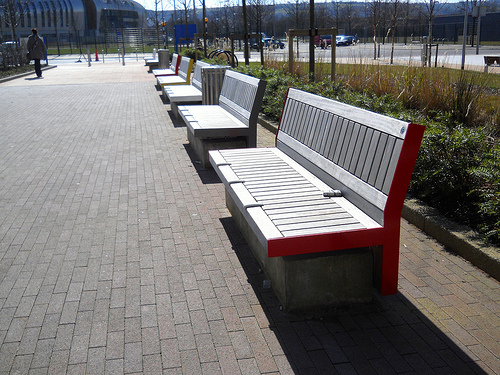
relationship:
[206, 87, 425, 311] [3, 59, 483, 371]
bench in pavilion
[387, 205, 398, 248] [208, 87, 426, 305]
paint on bench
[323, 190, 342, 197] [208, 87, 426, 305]
lock on bench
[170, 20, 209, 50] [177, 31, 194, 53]
blue sign on pole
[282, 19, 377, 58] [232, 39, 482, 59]
cars parked in lot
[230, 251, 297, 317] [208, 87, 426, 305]
debris under bench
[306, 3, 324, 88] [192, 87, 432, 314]
tree behind bench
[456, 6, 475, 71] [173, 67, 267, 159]
tree behind bench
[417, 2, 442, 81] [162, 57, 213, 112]
tree behind bench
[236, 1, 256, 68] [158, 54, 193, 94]
tree behind bench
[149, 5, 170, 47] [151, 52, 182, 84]
tree behind bench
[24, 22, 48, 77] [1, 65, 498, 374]
person walking down pathway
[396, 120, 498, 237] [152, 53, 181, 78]
green plants behind bench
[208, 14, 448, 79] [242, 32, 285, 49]
street for car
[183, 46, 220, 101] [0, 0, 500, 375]
can on outside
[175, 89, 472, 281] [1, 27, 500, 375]
bench on pathway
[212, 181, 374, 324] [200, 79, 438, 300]
block on bench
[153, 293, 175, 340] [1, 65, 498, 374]
bricks on pathway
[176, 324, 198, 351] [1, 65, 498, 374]
bricks on pathway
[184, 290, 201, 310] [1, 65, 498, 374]
bricks on pathway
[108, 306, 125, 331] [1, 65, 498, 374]
bricks on pathway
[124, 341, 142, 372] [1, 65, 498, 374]
bricks on pathway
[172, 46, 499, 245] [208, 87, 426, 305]
bushes behind bench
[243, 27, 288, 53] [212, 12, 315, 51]
car in background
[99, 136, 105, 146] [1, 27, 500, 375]
brick on pathway